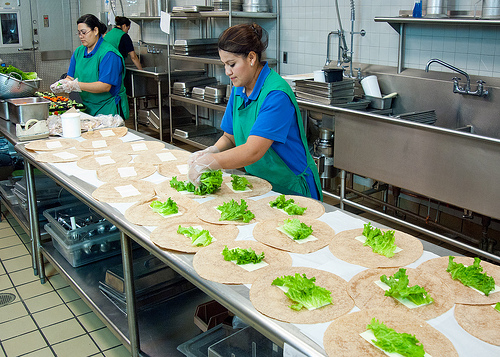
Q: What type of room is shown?
A: It is a kitchen.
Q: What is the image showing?
A: It is showing a kitchen.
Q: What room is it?
A: It is a kitchen.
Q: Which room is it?
A: It is a kitchen.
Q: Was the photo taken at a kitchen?
A: Yes, it was taken in a kitchen.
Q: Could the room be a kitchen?
A: Yes, it is a kitchen.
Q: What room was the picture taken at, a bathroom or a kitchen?
A: It was taken at a kitchen.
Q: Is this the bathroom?
A: No, it is the kitchen.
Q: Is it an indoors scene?
A: Yes, it is indoors.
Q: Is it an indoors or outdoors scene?
A: It is indoors.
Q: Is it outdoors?
A: No, it is indoors.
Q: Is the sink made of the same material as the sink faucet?
A: Yes, both the sink and the faucet are made of metal.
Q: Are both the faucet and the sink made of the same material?
A: Yes, both the faucet and the sink are made of metal.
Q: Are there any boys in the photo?
A: No, there are no boys.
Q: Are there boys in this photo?
A: No, there are no boys.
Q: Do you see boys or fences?
A: No, there are no boys or fences.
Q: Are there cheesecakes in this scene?
A: No, there are no cheesecakes.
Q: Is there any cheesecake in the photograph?
A: No, there are no cheesecakes.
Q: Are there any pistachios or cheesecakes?
A: No, there are no cheesecakes or pistachios.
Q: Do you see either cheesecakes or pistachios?
A: No, there are no cheesecakes or pistachios.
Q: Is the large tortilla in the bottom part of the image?
A: Yes, the tortilla is in the bottom of the image.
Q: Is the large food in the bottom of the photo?
A: Yes, the tortilla is in the bottom of the image.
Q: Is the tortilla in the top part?
A: No, the tortilla is in the bottom of the image.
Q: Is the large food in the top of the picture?
A: No, the tortilla is in the bottom of the image.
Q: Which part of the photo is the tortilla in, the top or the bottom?
A: The tortilla is in the bottom of the image.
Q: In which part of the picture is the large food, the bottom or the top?
A: The tortilla is in the bottom of the image.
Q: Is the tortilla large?
A: Yes, the tortilla is large.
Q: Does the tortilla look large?
A: Yes, the tortilla is large.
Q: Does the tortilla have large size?
A: Yes, the tortilla is large.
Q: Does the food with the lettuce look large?
A: Yes, the tortilla is large.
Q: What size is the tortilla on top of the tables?
A: The tortilla is large.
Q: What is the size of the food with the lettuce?
A: The tortilla is large.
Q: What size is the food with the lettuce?
A: The tortilla is large.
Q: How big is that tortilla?
A: The tortilla is large.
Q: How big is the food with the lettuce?
A: The tortilla is large.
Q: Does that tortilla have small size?
A: No, the tortilla is large.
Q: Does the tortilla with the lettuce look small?
A: No, the tortilla is large.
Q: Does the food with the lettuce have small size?
A: No, the tortilla is large.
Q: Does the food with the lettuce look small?
A: No, the tortilla is large.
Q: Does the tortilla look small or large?
A: The tortilla is large.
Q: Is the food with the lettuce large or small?
A: The tortilla is large.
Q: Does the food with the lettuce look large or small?
A: The tortilla is large.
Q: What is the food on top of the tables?
A: The food is a tortilla.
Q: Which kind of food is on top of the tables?
A: The food is a tortilla.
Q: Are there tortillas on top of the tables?
A: Yes, there is a tortilla on top of the tables.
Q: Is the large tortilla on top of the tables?
A: Yes, the tortilla is on top of the tables.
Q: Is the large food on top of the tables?
A: Yes, the tortilla is on top of the tables.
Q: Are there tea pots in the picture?
A: No, there are no tea pots.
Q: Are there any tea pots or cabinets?
A: No, there are no tea pots or cabinets.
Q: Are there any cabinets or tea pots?
A: No, there are no tea pots or cabinets.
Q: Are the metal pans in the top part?
A: Yes, the pans are in the top of the image.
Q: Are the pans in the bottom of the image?
A: No, the pans are in the top of the image.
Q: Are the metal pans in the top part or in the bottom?
A: The pans are in the top of the image.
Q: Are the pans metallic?
A: Yes, the pans are metallic.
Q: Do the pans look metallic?
A: Yes, the pans are metallic.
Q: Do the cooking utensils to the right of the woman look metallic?
A: Yes, the pans are metallic.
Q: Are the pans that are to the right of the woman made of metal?
A: Yes, the pans are made of metal.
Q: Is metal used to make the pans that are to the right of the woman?
A: Yes, the pans are made of metal.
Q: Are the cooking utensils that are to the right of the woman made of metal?
A: Yes, the pans are made of metal.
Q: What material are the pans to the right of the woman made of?
A: The pans are made of metal.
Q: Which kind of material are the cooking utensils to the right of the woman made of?
A: The pans are made of metal.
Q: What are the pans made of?
A: The pans are made of metal.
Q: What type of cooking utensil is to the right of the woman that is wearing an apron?
A: The cooking utensils are pans.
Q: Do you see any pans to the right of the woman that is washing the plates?
A: Yes, there are pans to the right of the woman.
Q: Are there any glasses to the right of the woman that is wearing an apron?
A: No, there are pans to the right of the woman.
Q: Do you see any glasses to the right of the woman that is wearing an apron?
A: No, there are pans to the right of the woman.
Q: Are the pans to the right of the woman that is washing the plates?
A: Yes, the pans are to the right of the woman.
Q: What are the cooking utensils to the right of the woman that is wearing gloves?
A: The cooking utensils are pans.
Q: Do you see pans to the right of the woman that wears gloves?
A: Yes, there are pans to the right of the woman.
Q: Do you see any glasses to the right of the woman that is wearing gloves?
A: No, there are pans to the right of the woman.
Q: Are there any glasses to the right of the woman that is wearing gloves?
A: No, there are pans to the right of the woman.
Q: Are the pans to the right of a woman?
A: Yes, the pans are to the right of a woman.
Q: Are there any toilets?
A: No, there are no toilets.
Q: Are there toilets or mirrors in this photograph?
A: No, there are no toilets or mirrors.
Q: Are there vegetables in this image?
A: Yes, there are vegetables.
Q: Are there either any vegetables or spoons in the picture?
A: Yes, there are vegetables.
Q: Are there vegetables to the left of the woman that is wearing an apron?
A: Yes, there are vegetables to the left of the woman.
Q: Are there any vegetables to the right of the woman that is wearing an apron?
A: No, the vegetables are to the left of the woman.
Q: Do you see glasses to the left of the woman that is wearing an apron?
A: No, there are vegetables to the left of the woman.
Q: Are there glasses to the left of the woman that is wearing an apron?
A: No, there are vegetables to the left of the woman.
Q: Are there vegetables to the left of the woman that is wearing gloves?
A: Yes, there are vegetables to the left of the woman.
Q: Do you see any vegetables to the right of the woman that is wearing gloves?
A: No, the vegetables are to the left of the woman.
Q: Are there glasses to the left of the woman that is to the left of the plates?
A: No, there are vegetables to the left of the woman.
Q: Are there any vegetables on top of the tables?
A: Yes, there are vegetables on top of the tables.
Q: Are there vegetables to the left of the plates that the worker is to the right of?
A: Yes, there are vegetables to the left of the plates.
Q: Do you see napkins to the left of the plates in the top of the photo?
A: No, there are vegetables to the left of the plates.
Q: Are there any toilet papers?
A: No, there are no toilet papers.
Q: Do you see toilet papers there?
A: No, there are no toilet papers.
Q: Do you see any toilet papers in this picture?
A: No, there are no toilet papers.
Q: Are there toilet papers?
A: No, there are no toilet papers.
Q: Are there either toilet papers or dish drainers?
A: No, there are no toilet papers or dish drainers.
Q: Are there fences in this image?
A: No, there are no fences.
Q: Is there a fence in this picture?
A: No, there are no fences.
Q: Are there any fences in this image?
A: No, there are no fences.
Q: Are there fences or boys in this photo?
A: No, there are no fences or boys.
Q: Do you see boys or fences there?
A: No, there are no fences or boys.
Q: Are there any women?
A: Yes, there is a woman.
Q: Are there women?
A: Yes, there is a woman.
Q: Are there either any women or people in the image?
A: Yes, there is a woman.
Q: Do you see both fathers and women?
A: No, there is a woman but no fathers.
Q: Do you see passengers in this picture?
A: No, there are no passengers.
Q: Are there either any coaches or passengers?
A: No, there are no passengers or coaches.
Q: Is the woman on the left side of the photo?
A: Yes, the woman is on the left of the image.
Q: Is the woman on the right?
A: No, the woman is on the left of the image.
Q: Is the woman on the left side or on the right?
A: The woman is on the left of the image.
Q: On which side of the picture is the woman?
A: The woman is on the left of the image.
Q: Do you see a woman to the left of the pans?
A: Yes, there is a woman to the left of the pans.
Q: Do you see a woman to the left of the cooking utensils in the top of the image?
A: Yes, there is a woman to the left of the pans.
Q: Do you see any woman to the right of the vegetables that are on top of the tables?
A: Yes, there is a woman to the right of the vegetables.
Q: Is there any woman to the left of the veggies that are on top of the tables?
A: No, the woman is to the right of the vegetables.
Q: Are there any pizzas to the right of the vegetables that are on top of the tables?
A: No, there is a woman to the right of the veggies.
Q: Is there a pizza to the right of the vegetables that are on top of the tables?
A: No, there is a woman to the right of the veggies.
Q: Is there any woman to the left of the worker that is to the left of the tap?
A: Yes, there is a woman to the left of the worker.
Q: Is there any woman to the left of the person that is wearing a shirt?
A: Yes, there is a woman to the left of the worker.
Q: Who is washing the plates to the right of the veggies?
A: The woman is washing the plates.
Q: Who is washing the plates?
A: The woman is washing the plates.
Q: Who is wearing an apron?
A: The woman is wearing an apron.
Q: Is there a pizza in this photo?
A: No, there are no pizzas.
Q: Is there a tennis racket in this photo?
A: No, there are no rackets.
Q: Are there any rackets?
A: No, there are no rackets.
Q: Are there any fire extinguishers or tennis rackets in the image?
A: No, there are no tennis rackets or fire extinguishers.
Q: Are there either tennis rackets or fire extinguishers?
A: No, there are no tennis rackets or fire extinguishers.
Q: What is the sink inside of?
A: The sink is inside the kitchen.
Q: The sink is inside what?
A: The sink is inside the kitchen.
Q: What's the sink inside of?
A: The sink is inside the kitchen.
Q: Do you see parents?
A: No, there are no parents.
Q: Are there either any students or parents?
A: No, there are no parents or students.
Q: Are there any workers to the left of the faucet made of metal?
A: Yes, there is a worker to the left of the tap.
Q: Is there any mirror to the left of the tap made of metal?
A: No, there is a worker to the left of the faucet.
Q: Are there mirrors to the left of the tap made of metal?
A: No, there is a worker to the left of the faucet.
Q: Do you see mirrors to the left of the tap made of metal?
A: No, there is a worker to the left of the faucet.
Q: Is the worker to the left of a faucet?
A: Yes, the worker is to the left of a faucet.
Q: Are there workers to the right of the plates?
A: Yes, there is a worker to the right of the plates.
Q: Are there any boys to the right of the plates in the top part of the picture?
A: No, there is a worker to the right of the plates.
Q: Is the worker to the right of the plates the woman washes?
A: Yes, the worker is to the right of the plates.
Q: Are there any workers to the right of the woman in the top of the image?
A: Yes, there is a worker to the right of the woman.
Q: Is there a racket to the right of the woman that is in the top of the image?
A: No, there is a worker to the right of the woman.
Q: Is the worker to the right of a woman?
A: Yes, the worker is to the right of a woman.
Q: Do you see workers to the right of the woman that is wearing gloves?
A: Yes, there is a worker to the right of the woman.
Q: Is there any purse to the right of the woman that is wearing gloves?
A: No, there is a worker to the right of the woman.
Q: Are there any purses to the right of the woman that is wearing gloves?
A: No, there is a worker to the right of the woman.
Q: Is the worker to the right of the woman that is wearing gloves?
A: Yes, the worker is to the right of the woman.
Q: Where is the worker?
A: The worker is in the kitchen.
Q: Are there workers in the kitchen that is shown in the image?
A: Yes, there is a worker in the kitchen.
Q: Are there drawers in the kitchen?
A: No, there is a worker in the kitchen.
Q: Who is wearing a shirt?
A: The worker is wearing a shirt.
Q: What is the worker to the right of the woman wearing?
A: The worker is wearing a shirt.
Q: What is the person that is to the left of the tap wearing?
A: The worker is wearing a shirt.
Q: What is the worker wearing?
A: The worker is wearing a shirt.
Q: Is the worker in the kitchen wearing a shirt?
A: Yes, the worker is wearing a shirt.